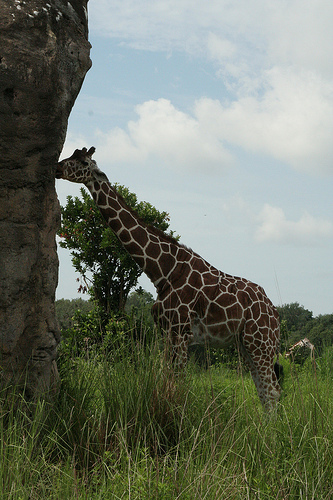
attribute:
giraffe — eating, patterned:
[55, 146, 284, 417]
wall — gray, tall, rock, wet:
[1, 2, 94, 414]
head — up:
[53, 145, 102, 185]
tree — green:
[59, 182, 181, 352]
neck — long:
[80, 177, 185, 293]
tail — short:
[271, 337, 286, 384]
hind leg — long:
[238, 306, 283, 416]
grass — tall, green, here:
[1, 326, 332, 499]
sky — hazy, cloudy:
[57, 1, 332, 308]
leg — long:
[156, 299, 187, 414]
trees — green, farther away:
[51, 288, 331, 357]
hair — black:
[271, 362, 283, 383]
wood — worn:
[281, 337, 316, 367]